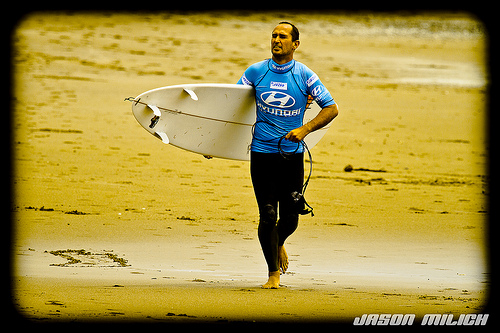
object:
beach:
[17, 13, 483, 325]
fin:
[147, 88, 199, 144]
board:
[124, 83, 339, 162]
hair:
[278, 22, 299, 42]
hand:
[285, 127, 309, 143]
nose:
[274, 35, 280, 44]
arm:
[304, 67, 339, 132]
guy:
[203, 21, 339, 289]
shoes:
[260, 246, 288, 289]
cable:
[251, 120, 316, 217]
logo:
[260, 91, 295, 109]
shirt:
[236, 59, 336, 154]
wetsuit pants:
[250, 150, 304, 272]